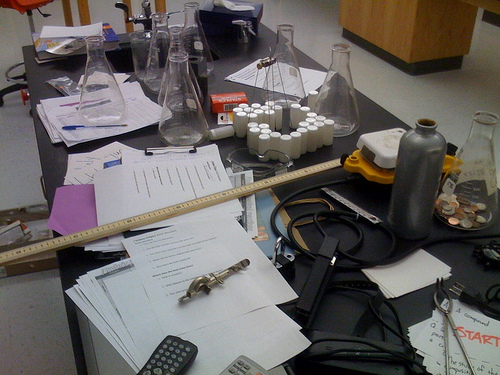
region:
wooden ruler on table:
[3, 148, 352, 277]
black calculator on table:
[131, 323, 196, 373]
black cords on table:
[269, 184, 408, 373]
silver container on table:
[388, 113, 460, 237]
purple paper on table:
[44, 174, 92, 238]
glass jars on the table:
[75, 4, 362, 144]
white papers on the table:
[32, 81, 496, 373]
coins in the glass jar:
[437, 184, 488, 236]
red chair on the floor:
[0, 1, 62, 108]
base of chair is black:
[5, 13, 61, 114]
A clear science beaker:
[158, 50, 209, 142]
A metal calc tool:
[175, 259, 250, 309]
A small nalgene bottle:
[377, 116, 453, 243]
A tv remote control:
[125, 331, 197, 373]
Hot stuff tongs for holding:
[428, 278, 475, 372]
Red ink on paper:
[451, 322, 498, 345]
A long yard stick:
[3, 157, 344, 260]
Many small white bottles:
[221, 91, 336, 160]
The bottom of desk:
[342, 0, 478, 76]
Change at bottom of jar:
[433, 179, 493, 227]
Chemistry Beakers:
[78, 3, 228, 151]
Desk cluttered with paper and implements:
[25, 135, 380, 372]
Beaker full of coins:
[431, 103, 498, 235]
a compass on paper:
[162, 235, 274, 320]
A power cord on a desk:
[246, 175, 415, 373]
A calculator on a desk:
[128, 326, 212, 372]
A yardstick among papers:
[6, 135, 391, 276]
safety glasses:
[213, 133, 305, 183]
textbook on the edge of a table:
[27, 6, 152, 78]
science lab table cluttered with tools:
[73, 25, 483, 373]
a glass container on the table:
[425, 96, 497, 251]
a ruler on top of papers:
[12, 152, 361, 276]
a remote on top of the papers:
[115, 322, 199, 370]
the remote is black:
[134, 324, 199, 373]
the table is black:
[176, 16, 393, 203]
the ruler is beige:
[79, 169, 339, 262]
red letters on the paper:
[442, 313, 495, 355]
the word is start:
[452, 313, 497, 354]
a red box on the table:
[203, 82, 258, 121]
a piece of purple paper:
[32, 154, 127, 254]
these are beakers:
[137, 46, 204, 122]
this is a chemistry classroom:
[63, 77, 328, 365]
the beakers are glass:
[166, 93, 225, 136]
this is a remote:
[89, 307, 144, 373]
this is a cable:
[253, 246, 365, 288]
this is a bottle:
[331, 43, 458, 203]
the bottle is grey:
[421, 159, 455, 191]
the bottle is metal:
[430, 159, 487, 266]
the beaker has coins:
[383, 164, 448, 179]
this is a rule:
[260, 167, 288, 227]